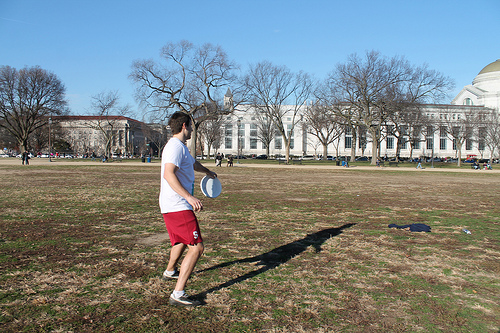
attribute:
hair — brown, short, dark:
[162, 106, 201, 144]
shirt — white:
[157, 133, 204, 214]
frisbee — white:
[193, 172, 229, 200]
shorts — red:
[163, 208, 210, 247]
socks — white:
[160, 264, 188, 296]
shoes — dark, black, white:
[163, 261, 197, 311]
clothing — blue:
[384, 220, 437, 240]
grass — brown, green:
[355, 240, 484, 309]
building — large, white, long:
[184, 57, 499, 158]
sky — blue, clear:
[15, 4, 492, 70]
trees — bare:
[1, 41, 497, 173]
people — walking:
[209, 150, 243, 174]